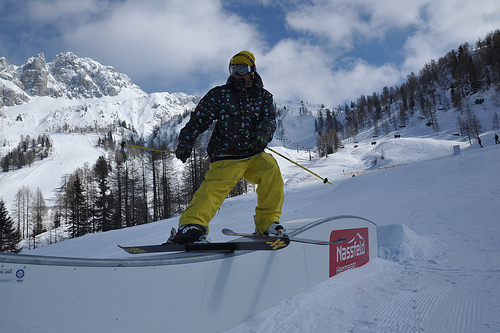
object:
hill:
[6, 42, 118, 132]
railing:
[0, 213, 425, 279]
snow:
[22, 79, 106, 152]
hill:
[0, 142, 499, 333]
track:
[0, 129, 108, 224]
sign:
[328, 224, 370, 277]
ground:
[375, 160, 413, 195]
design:
[267, 239, 287, 253]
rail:
[2, 146, 499, 331]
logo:
[328, 227, 370, 276]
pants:
[178, 151, 284, 235]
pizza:
[118, 44, 338, 276]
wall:
[268, 111, 299, 146]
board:
[117, 230, 292, 251]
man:
[175, 50, 288, 245]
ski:
[117, 233, 294, 255]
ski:
[218, 226, 346, 243]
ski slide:
[0, 200, 376, 298]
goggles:
[229, 65, 257, 76]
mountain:
[1, 28, 500, 333]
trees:
[312, 28, 500, 156]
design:
[223, 94, 266, 128]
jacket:
[174, 50, 276, 164]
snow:
[0, 144, 499, 333]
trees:
[0, 130, 248, 254]